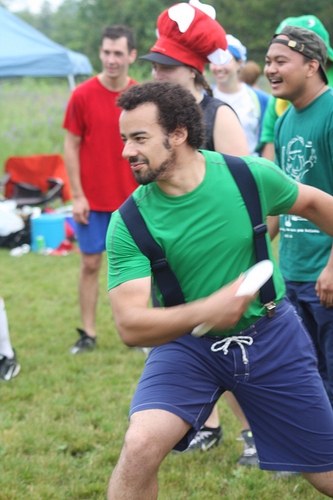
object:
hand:
[207, 268, 256, 333]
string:
[209, 334, 255, 366]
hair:
[113, 78, 206, 153]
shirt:
[104, 148, 298, 339]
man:
[102, 81, 332, 499]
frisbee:
[189, 258, 275, 339]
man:
[60, 24, 150, 357]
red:
[89, 103, 118, 173]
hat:
[137, 0, 229, 76]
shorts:
[126, 299, 332, 472]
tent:
[0, 0, 94, 159]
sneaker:
[0, 348, 23, 383]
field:
[21, 283, 120, 444]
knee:
[118, 431, 161, 469]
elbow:
[114, 303, 151, 352]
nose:
[121, 137, 139, 160]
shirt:
[62, 72, 142, 214]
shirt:
[204, 78, 272, 164]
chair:
[19, 132, 64, 195]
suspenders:
[218, 153, 278, 320]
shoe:
[68, 325, 100, 359]